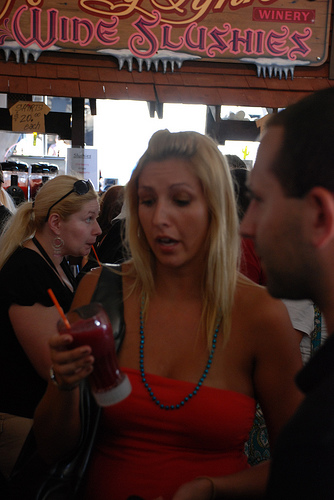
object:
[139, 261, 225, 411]
necklace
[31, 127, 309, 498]
woman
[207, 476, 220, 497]
bracelet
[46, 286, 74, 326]
straw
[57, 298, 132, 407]
cup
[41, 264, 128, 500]
purse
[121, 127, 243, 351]
hair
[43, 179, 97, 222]
sunglasses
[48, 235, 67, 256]
earring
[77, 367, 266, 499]
top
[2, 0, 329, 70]
sign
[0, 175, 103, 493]
lady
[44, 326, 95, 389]
hand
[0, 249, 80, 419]
blouse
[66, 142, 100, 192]
paper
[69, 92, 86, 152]
post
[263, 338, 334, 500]
shirt